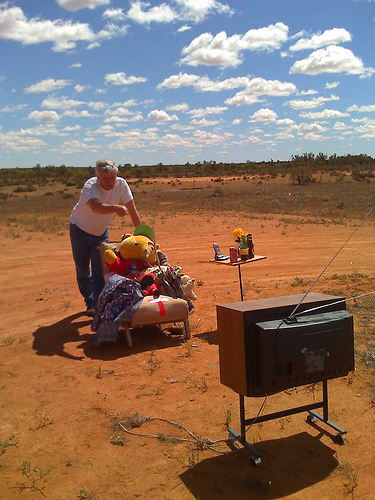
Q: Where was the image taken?
A: It was taken at the desert.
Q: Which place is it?
A: It is a desert.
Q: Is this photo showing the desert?
A: Yes, it is showing the desert.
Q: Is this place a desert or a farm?
A: It is a desert.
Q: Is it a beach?
A: No, it is a desert.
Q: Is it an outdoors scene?
A: Yes, it is outdoors.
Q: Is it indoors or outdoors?
A: It is outdoors.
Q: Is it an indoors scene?
A: No, it is outdoors.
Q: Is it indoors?
A: No, it is outdoors.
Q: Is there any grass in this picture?
A: Yes, there is grass.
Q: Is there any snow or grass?
A: Yes, there is grass.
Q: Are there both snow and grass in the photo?
A: No, there is grass but no snow.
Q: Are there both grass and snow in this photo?
A: No, there is grass but no snow.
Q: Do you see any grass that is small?
A: Yes, there is small grass.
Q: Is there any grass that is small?
A: Yes, there is grass that is small.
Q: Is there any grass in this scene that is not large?
A: Yes, there is small grass.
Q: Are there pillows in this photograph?
A: No, there are no pillows.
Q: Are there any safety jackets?
A: No, there are no safety jackets.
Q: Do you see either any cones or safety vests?
A: No, there are no safety vests or cones.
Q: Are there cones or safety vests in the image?
A: No, there are no safety vests or cones.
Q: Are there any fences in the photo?
A: No, there are no fences.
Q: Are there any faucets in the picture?
A: No, there are no faucets.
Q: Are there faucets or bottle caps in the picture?
A: No, there are no faucets or bottle caps.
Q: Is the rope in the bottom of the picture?
A: Yes, the rope is in the bottom of the image.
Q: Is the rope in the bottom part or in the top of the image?
A: The rope is in the bottom of the image.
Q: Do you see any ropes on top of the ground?
A: Yes, there is a rope on top of the ground.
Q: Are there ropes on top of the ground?
A: Yes, there is a rope on top of the ground.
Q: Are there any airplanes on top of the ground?
A: No, there is a rope on top of the ground.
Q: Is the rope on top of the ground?
A: Yes, the rope is on top of the ground.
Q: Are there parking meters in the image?
A: No, there are no parking meters.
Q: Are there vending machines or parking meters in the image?
A: No, there are no parking meters or vending machines.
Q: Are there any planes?
A: No, there are no planes.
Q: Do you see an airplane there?
A: No, there are no airplanes.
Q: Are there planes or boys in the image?
A: No, there are no planes or boys.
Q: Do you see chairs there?
A: Yes, there is a chair.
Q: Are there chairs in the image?
A: Yes, there is a chair.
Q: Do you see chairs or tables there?
A: Yes, there is a chair.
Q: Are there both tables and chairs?
A: Yes, there are both a chair and a table.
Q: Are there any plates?
A: No, there are no plates.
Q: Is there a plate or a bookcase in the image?
A: No, there are no plates or bookcases.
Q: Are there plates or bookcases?
A: No, there are no plates or bookcases.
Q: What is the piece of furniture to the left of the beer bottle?
A: The piece of furniture is a chair.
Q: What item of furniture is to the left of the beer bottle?
A: The piece of furniture is a chair.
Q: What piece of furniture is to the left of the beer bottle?
A: The piece of furniture is a chair.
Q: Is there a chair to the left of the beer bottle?
A: Yes, there is a chair to the left of the beer bottle.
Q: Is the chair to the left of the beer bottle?
A: Yes, the chair is to the left of the beer bottle.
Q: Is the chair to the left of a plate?
A: No, the chair is to the left of the beer bottle.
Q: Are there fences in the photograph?
A: No, there are no fences.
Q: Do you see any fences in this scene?
A: No, there are no fences.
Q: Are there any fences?
A: No, there are no fences.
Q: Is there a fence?
A: No, there are no fences.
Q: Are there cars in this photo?
A: No, there are no cars.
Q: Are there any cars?
A: No, there are no cars.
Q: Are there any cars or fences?
A: No, there are no cars or fences.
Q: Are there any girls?
A: No, there are no girls.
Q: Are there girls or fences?
A: No, there are no girls or fences.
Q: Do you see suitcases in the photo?
A: No, there are no suitcases.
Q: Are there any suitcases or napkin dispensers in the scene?
A: No, there are no suitcases or napkin dispensers.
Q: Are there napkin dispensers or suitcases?
A: No, there are no suitcases or napkin dispensers.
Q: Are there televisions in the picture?
A: Yes, there is a television.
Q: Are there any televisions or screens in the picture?
A: Yes, there is a television.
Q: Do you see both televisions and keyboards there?
A: No, there is a television but no keyboards.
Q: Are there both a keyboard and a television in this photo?
A: No, there is a television but no keyboards.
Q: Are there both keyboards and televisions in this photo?
A: No, there is a television but no keyboards.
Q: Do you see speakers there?
A: No, there are no speakers.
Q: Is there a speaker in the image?
A: No, there are no speakers.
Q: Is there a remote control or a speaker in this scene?
A: No, there are no speakers or remote controls.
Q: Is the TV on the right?
A: Yes, the TV is on the right of the image.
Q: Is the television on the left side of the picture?
A: No, the television is on the right of the image.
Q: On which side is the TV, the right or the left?
A: The TV is on the right of the image.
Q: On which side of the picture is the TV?
A: The TV is on the right of the image.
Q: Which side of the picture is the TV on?
A: The TV is on the right of the image.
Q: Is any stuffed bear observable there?
A: Yes, there is a stuffed bear.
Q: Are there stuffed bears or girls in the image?
A: Yes, there is a stuffed bear.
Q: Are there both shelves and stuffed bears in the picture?
A: No, there is a stuffed bear but no shelves.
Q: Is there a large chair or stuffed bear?
A: Yes, there is a large stuffed bear.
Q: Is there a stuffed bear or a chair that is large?
A: Yes, the stuffed bear is large.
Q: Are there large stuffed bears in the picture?
A: Yes, there is a large stuffed bear.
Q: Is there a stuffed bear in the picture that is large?
A: Yes, there is a stuffed bear that is large.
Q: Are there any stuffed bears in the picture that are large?
A: Yes, there is a stuffed bear that is large.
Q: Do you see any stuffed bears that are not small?
A: Yes, there is a large stuffed bear.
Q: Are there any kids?
A: No, there are no kids.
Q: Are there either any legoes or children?
A: No, there are no children or legoes.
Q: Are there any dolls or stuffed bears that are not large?
A: No, there is a stuffed bear but it is large.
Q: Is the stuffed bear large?
A: Yes, the stuffed bear is large.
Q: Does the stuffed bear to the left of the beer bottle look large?
A: Yes, the stuffed bear is large.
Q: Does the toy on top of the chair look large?
A: Yes, the stuffed bear is large.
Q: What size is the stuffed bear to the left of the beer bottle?
A: The stuffed bear is large.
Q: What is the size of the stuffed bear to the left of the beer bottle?
A: The stuffed bear is large.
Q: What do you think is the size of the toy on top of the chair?
A: The stuffed bear is large.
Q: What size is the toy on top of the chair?
A: The stuffed bear is large.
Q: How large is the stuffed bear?
A: The stuffed bear is large.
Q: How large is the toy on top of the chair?
A: The stuffed bear is large.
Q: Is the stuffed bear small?
A: No, the stuffed bear is large.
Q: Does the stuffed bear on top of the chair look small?
A: No, the stuffed bear is large.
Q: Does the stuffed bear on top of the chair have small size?
A: No, the stuffed bear is large.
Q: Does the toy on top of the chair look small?
A: No, the stuffed bear is large.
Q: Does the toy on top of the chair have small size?
A: No, the stuffed bear is large.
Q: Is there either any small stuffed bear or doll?
A: No, there is a stuffed bear but it is large.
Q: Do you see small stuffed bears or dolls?
A: No, there is a stuffed bear but it is large.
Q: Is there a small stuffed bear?
A: No, there is a stuffed bear but it is large.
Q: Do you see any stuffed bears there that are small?
A: No, there is a stuffed bear but it is large.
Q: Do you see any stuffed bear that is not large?
A: No, there is a stuffed bear but it is large.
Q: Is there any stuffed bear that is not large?
A: No, there is a stuffed bear but it is large.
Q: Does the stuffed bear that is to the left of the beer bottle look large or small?
A: The stuffed bear is large.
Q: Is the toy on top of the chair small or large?
A: The stuffed bear is large.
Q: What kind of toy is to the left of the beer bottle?
A: The toy is a stuffed bear.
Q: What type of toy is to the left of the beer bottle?
A: The toy is a stuffed bear.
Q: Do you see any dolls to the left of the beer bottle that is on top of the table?
A: No, there is a stuffed bear to the left of the beer bottle.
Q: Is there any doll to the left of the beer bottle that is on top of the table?
A: No, there is a stuffed bear to the left of the beer bottle.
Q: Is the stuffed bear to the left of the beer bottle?
A: Yes, the stuffed bear is to the left of the beer bottle.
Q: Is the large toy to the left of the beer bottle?
A: Yes, the stuffed bear is to the left of the beer bottle.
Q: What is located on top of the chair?
A: The stuffed bear is on top of the chair.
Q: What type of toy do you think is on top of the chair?
A: The toy is a stuffed bear.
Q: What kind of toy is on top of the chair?
A: The toy is a stuffed bear.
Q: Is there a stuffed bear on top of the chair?
A: Yes, there is a stuffed bear on top of the chair.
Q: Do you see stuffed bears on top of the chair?
A: Yes, there is a stuffed bear on top of the chair.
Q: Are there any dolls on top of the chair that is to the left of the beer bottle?
A: No, there is a stuffed bear on top of the chair.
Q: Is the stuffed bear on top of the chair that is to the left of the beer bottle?
A: Yes, the stuffed bear is on top of the chair.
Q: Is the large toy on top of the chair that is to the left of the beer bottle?
A: Yes, the stuffed bear is on top of the chair.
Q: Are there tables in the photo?
A: Yes, there is a table.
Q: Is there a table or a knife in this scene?
A: Yes, there is a table.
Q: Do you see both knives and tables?
A: No, there is a table but no knives.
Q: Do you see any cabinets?
A: No, there are no cabinets.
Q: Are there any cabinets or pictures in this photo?
A: No, there are no cabinets or pictures.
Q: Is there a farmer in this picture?
A: No, there are no farmers.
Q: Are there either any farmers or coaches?
A: No, there are no farmers or coaches.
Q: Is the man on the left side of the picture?
A: Yes, the man is on the left of the image.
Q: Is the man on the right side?
A: No, the man is on the left of the image.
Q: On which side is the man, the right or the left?
A: The man is on the left of the image.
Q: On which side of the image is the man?
A: The man is on the left of the image.